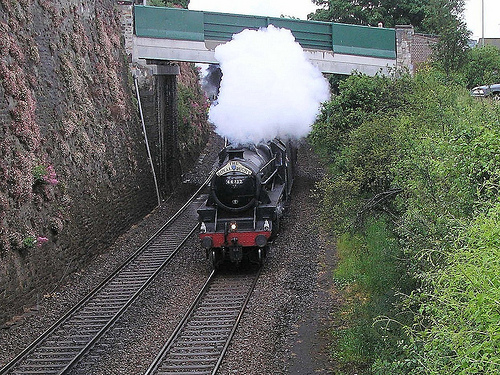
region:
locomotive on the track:
[197, 109, 321, 294]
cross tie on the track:
[172, 336, 219, 348]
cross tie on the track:
[179, 323, 226, 333]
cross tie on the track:
[163, 350, 216, 362]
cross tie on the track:
[49, 325, 105, 337]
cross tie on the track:
[85, 301, 118, 308]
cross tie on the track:
[181, 319, 226, 327]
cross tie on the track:
[194, 299, 240, 311]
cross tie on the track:
[187, 308, 239, 318]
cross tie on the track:
[152, 355, 217, 368]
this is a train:
[210, 121, 335, 274]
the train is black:
[210, 91, 292, 266]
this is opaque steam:
[177, 15, 297, 130]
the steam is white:
[225, 65, 290, 130]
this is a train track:
[56, 211, 279, 361]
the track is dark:
[153, 275, 293, 360]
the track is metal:
[176, 306, 252, 362]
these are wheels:
[168, 236, 263, 268]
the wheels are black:
[220, 250, 298, 298]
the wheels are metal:
[196, 251, 239, 271]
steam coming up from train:
[199, 24, 336, 152]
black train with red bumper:
[192, 118, 299, 280]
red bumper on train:
[199, 227, 270, 250]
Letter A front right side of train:
[261, 219, 272, 229]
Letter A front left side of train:
[197, 221, 208, 233]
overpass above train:
[131, 0, 445, 88]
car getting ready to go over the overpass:
[467, 74, 499, 98]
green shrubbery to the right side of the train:
[318, 65, 498, 372]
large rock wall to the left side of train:
[1, 1, 210, 325]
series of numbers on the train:
[222, 177, 243, 187]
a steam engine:
[161, 69, 324, 286]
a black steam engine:
[171, 77, 323, 292]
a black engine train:
[181, 77, 325, 294]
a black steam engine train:
[185, 97, 332, 284]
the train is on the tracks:
[178, 89, 342, 317]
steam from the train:
[193, 11, 339, 142]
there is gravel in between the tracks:
[2, 239, 285, 371]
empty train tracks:
[1, 195, 199, 374]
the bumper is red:
[190, 218, 281, 260]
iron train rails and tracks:
[135, 268, 264, 374]